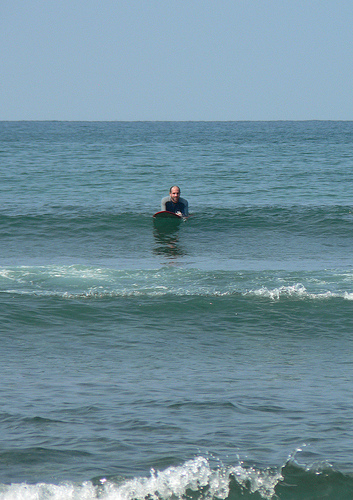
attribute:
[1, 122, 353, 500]
water — splashing, wavy, blue, engaging, ripply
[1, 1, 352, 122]
sky — gray, blue, cloudless, clear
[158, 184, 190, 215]
man — surfing alone, waiting for wave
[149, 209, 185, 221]
surfboard — red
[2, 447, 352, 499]
wave — white, blue, closer, bigger, small, breaking near shore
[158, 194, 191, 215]
wet suit — gray, blue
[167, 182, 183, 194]
hairline — receding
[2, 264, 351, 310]
wave — white, blue, small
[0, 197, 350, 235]
wave — white, blue, small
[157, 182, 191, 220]
surfer — a male, male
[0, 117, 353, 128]
coastline — between ocean andsky